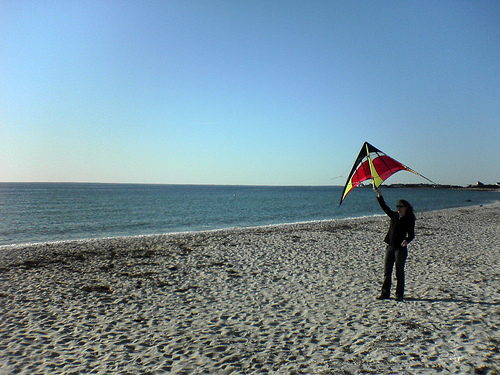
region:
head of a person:
[394, 190, 414, 215]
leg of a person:
[372, 245, 397, 295]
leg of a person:
[389, 256, 419, 289]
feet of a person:
[370, 290, 387, 300]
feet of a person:
[388, 288, 417, 312]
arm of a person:
[370, 190, 394, 220]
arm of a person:
[405, 224, 425, 241]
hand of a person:
[374, 174, 390, 195]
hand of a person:
[399, 230, 423, 251]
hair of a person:
[406, 187, 422, 212]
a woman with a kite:
[336, 135, 446, 303]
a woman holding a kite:
[332, 125, 437, 311]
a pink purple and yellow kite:
[333, 141, 431, 210]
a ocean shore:
[7, 208, 379, 256]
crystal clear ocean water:
[16, 185, 323, 240]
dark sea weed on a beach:
[15, 222, 231, 302]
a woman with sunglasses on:
[395, 197, 405, 212]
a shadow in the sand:
[396, 285, 491, 306]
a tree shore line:
[420, 176, 497, 186]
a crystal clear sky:
[3, 2, 380, 140]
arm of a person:
[370, 172, 421, 218]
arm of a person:
[397, 214, 432, 242]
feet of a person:
[372, 287, 389, 307]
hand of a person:
[368, 177, 385, 191]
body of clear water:
[58, 199, 180, 235]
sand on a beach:
[134, 253, 269, 325]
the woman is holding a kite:
[308, 105, 433, 326]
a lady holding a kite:
[332, 92, 454, 317]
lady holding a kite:
[317, 103, 449, 305]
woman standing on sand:
[313, 110, 425, 339]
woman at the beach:
[307, 111, 443, 318]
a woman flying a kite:
[304, 87, 457, 312]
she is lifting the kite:
[315, 110, 482, 335]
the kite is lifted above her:
[309, 105, 499, 326]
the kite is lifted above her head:
[310, 65, 447, 331]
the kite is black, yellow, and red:
[306, 110, 465, 215]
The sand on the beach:
[10, 265, 345, 360]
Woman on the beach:
[195, 135, 490, 320]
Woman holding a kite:
[320, 130, 445, 305]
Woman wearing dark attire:
[365, 175, 420, 300]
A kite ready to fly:
[320, 135, 435, 205]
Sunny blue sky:
[0, 0, 320, 175]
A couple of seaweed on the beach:
[5, 245, 165, 275]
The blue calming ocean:
[5, 185, 271, 220]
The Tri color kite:
[322, 137, 437, 207]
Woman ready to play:
[305, 123, 455, 305]